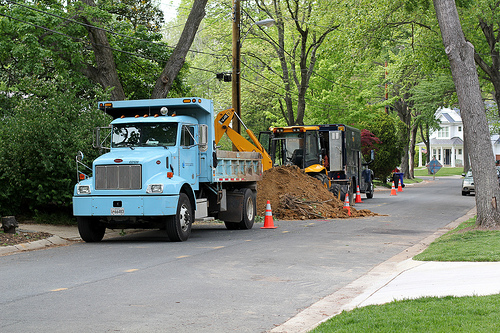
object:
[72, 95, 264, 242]
dump truck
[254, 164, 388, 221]
dirt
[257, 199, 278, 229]
cone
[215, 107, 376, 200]
road machine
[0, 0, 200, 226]
trees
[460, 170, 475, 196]
car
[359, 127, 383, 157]
tree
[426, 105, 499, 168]
house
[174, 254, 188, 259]
lines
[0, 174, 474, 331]
street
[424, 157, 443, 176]
sign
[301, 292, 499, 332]
grass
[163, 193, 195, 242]
tire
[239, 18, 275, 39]
street lamp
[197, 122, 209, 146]
mirror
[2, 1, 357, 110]
lines